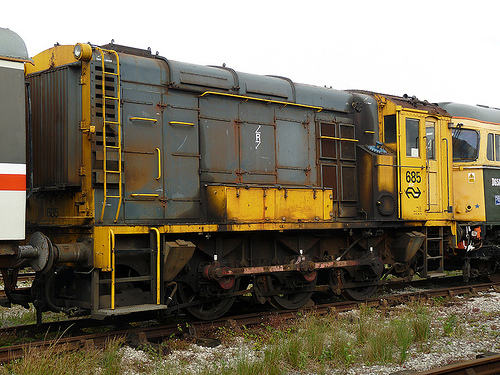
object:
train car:
[2, 25, 52, 252]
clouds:
[1, 2, 499, 105]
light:
[72, 42, 92, 60]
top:
[45, 42, 165, 67]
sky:
[0, 0, 500, 108]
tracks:
[418, 351, 500, 375]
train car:
[441, 102, 498, 276]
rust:
[262, 190, 269, 219]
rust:
[232, 122, 245, 183]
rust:
[27, 79, 64, 176]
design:
[254, 125, 262, 149]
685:
[406, 170, 422, 183]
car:
[24, 38, 441, 321]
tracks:
[0, 275, 497, 362]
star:
[475, 203, 481, 209]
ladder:
[92, 46, 120, 222]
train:
[0, 29, 498, 321]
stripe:
[0, 174, 27, 191]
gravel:
[111, 286, 500, 375]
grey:
[1, 68, 28, 160]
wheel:
[176, 249, 237, 320]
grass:
[0, 296, 462, 373]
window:
[406, 117, 419, 158]